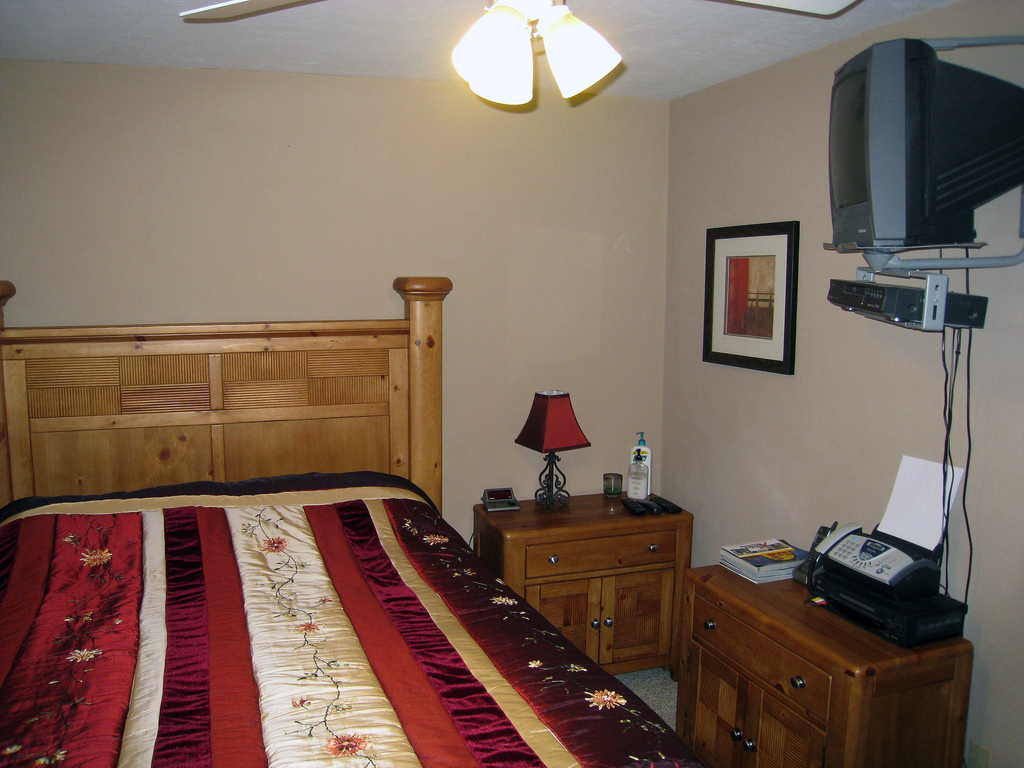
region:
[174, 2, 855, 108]
White ceiling lamp with illuminated globes.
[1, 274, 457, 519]
A brown wood head board.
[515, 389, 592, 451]
A red lamp shade.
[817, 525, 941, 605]
A black and white printer.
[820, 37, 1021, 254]
A grey and black television.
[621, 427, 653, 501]
Two bottles of lotion.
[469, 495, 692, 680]
A brown side table.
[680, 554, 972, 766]
A brown table with a printer on top.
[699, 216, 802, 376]
Black framed picture on the wall.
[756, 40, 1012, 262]
television on a stand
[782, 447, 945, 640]
printer on a cabinet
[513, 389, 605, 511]
lamp on a table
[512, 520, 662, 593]
table near a bed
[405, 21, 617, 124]
light in a ceiling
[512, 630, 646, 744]
flowers on a bed spread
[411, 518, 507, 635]
flowers on a bed spread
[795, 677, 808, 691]
A knob for a drawer.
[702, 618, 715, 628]
A knob for a drawer.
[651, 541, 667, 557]
A knob for a drawer.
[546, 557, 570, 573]
A knob for a drawer.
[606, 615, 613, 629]
A knob for a drawer.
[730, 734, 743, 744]
A knob for a drawer.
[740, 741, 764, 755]
A knob for a drawer.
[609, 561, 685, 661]
A door for a cabinet.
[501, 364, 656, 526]
the lamp is small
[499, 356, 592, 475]
the shade is red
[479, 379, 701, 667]
the lamp is on table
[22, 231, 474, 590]
a wood headboard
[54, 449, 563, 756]
the blanket is on bed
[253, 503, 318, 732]
flowers are on blanket